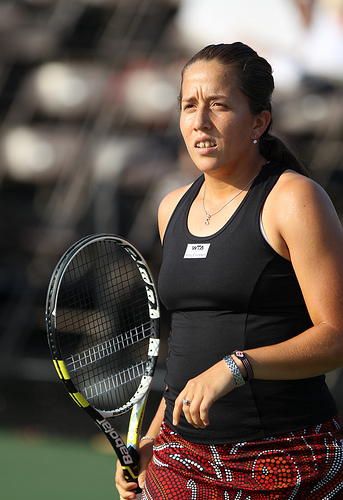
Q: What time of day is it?
A: Daytime.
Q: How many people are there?
A: One.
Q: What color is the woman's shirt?
A: Black.